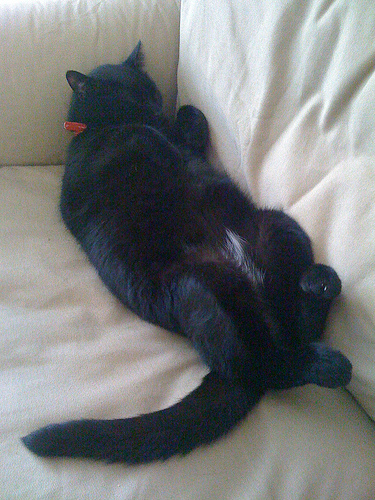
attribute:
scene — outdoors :
[7, 14, 28, 28]